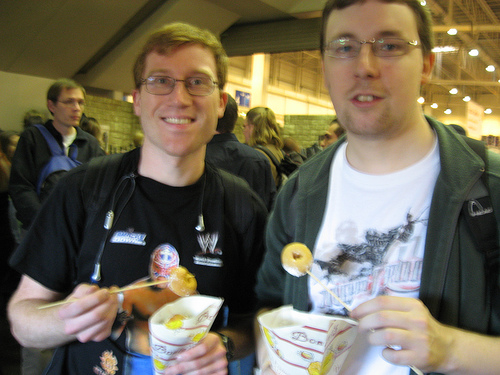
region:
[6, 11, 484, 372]
a scene inside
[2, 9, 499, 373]
two people posing for camera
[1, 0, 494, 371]
two white boys eating something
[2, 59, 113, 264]
a man in the background wearing black and blue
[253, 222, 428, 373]
a treat on a stick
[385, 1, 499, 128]
some lights in the distance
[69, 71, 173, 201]
a gray stone wall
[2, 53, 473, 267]
people walking around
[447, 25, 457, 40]
white light on ceiling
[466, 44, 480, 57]
white light on ceiling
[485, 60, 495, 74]
white light on ceiling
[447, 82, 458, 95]
white light on ceiling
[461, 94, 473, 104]
white light on ceiling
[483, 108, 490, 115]
white light on ceiling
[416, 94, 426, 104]
white light on ceiling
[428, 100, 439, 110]
white light on ceiling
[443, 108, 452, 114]
white light on ceiling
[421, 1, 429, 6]
white light on ceiling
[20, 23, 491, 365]
two men posing for camera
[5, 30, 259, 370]
man wearing black wrestling shirt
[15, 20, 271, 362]
man with glasses wearing black shirt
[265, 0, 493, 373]
man with white shirt and green jacket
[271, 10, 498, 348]
man holding thin stick with tiny donut on end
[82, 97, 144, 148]
gray brick wall behind people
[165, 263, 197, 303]
tiny yellow donut with powdered sugar on it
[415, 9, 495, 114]
lights hanging from ceiling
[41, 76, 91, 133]
the head of a man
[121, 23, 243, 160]
the head of a man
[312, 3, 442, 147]
the head of a man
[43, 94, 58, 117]
the ear of a man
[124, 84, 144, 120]
the ear of a man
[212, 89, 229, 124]
the ear of a man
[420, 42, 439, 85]
the ear of a man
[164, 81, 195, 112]
the nose of a man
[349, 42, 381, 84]
the nose of a man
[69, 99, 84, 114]
the nose of a man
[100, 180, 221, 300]
The black t-shirt the man is wearing.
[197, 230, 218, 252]
The W on the man's shirt.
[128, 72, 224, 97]
The eyeglasses the man on the left is wearing.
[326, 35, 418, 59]
The eyeglasses the man on the right is wearing.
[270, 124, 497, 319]
The green jacket the man on the right is wearing.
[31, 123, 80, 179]
The blue back pack the man is carrying.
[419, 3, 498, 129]
The hanging lights.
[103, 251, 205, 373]
The design of the wrestler on the man's shirt.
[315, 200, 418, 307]
The design on the man's white shirt.